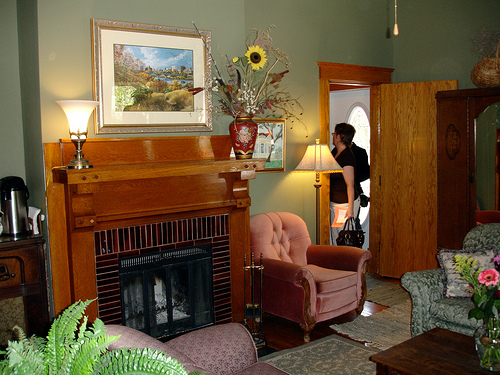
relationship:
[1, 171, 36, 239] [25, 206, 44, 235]
thermos of coffee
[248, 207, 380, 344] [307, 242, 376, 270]
chair has pink arm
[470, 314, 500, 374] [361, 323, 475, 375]
vase on table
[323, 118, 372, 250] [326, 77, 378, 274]
person standing in doorway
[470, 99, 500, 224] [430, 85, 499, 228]
mirror on a furniture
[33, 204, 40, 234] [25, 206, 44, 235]
napkin in holder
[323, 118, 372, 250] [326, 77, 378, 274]
lady in doorway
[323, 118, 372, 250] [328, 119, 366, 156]
lady has head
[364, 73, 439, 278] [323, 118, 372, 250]
door next to lady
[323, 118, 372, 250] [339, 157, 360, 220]
lady has arm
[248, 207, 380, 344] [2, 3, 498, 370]
couch in room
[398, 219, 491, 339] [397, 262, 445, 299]
couch has arm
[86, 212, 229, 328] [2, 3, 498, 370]
fireplace in room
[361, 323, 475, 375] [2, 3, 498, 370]
table in room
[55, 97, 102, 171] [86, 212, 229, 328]
lamp above fireplace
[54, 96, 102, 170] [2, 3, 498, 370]
lamp in room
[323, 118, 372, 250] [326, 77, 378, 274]
woman standing in doorway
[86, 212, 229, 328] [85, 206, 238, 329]
fireplace has bricks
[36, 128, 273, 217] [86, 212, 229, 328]
mantel above fireplace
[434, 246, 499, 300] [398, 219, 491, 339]
pillow on  piece of furniture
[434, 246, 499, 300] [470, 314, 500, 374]
flowers are on vase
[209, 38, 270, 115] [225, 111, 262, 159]
flowers in a vase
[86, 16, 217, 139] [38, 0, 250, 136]
picture hanging on wall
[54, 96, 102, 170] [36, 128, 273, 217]
lamp on mantle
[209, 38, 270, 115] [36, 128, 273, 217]
flowers are on mantle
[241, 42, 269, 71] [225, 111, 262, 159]
flowers in a vase